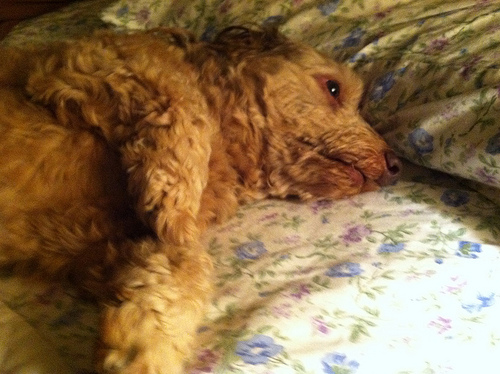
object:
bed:
[0, 0, 500, 373]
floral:
[233, 235, 269, 262]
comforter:
[231, 204, 499, 374]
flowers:
[405, 129, 435, 157]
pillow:
[99, 0, 499, 193]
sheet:
[0, 204, 499, 374]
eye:
[327, 79, 341, 99]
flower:
[235, 335, 282, 366]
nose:
[382, 151, 403, 186]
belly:
[3, 129, 104, 264]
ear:
[216, 19, 287, 54]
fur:
[1, 146, 62, 240]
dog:
[1, 25, 404, 371]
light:
[300, 244, 497, 373]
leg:
[34, 49, 211, 244]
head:
[216, 23, 401, 197]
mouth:
[319, 154, 369, 191]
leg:
[82, 241, 207, 373]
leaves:
[212, 269, 242, 289]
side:
[1, 39, 127, 273]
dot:
[330, 87, 335, 93]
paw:
[127, 170, 199, 239]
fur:
[268, 124, 315, 200]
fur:
[157, 26, 292, 81]